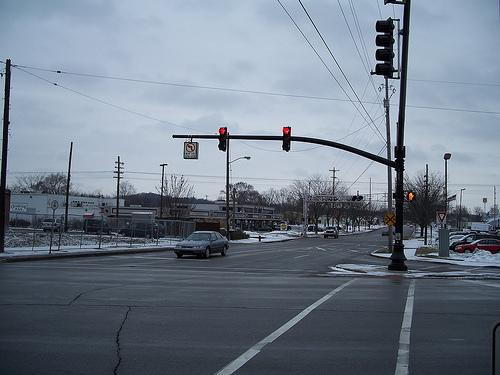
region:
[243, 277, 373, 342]
Painted line on the road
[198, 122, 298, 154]
Red light at an intersection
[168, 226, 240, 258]
Car stopped at an intersection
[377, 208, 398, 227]
Sign on the side of the road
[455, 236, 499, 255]
Red car in a parking lot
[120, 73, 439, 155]
Electric cables connected to poles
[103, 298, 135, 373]
Long crack in the pavement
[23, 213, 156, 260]
Old silver chicken wire fence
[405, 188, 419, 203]
Stop sign for pedestrians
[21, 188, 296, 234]
Buildings in the background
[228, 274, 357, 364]
white line on the ground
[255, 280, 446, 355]
two white lines on the ground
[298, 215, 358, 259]
car in the distance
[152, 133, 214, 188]
sign above the street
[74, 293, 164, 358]
crack in the street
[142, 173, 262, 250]
building in the distance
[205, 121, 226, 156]
red light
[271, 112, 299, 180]
red light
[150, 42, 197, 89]
white clouds in blue sky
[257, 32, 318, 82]
white clouds in blue sky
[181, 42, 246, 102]
white clouds in blue sky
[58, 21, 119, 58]
white clouds in blue sky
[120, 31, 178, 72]
white clouds in blue sky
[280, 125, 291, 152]
A stop light on a pole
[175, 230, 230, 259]
A car driving on a road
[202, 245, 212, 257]
A front left tire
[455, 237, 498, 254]
A red car parked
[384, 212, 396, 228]
A railroad crossing sign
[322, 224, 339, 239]
An SUV driving on the road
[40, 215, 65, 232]
Car that is parked in a space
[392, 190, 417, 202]
A walking light on a pole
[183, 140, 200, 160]
A white sign on a pole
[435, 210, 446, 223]
A red and white yield sign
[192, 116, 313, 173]
two red stop lights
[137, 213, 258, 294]
a car driving on the road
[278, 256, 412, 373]
white lines on the road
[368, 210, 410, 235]
a black and yellow traffic sign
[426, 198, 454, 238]
a red and white traffic sign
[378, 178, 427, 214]
a cross walk light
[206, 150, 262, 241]
street lights along side a road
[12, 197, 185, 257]
a metal fence along a road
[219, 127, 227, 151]
red stoplight on left side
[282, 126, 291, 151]
red stoplight on right side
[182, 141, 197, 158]
no left turn sign on pole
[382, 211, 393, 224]
yellow and black railroad crossing sign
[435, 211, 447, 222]
red and white yield sign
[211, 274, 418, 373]
double white crosswalk line on roadway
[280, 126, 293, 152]
a black traffic light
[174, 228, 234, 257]
a small car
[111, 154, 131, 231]
a tall electrical pole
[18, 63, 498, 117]
a long black electrical power line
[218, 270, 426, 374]
white street markings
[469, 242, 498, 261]
a pile of snow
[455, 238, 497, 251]
the side of a red car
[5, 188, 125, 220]
a small white building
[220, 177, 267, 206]
a tall tree with no leaves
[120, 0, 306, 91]
a large white cloud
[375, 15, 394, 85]
four street lights on a pole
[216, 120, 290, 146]
two red street lights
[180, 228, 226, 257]
a car on the road